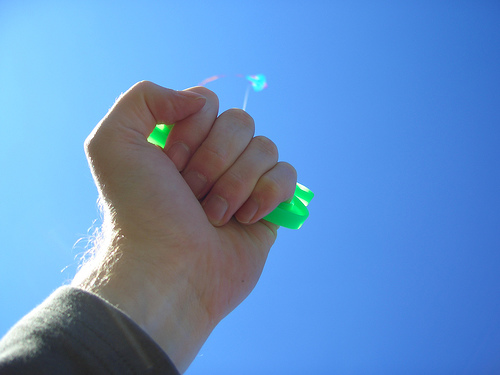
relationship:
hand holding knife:
[81, 78, 298, 308] [144, 117, 315, 235]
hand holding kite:
[81, 78, 298, 308] [195, 68, 268, 114]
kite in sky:
[195, 68, 268, 114] [0, 0, 499, 373]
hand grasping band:
[81, 78, 298, 308] [144, 117, 315, 235]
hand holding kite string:
[81, 78, 298, 308] [197, 69, 255, 115]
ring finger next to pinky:
[205, 135, 280, 231] [235, 159, 297, 225]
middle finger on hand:
[175, 107, 256, 205] [81, 78, 298, 308]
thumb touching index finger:
[94, 82, 206, 145] [163, 80, 219, 176]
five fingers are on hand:
[124, 77, 298, 192] [81, 78, 298, 308]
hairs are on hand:
[49, 197, 110, 283] [81, 78, 298, 308]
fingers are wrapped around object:
[124, 77, 298, 192] [144, 117, 315, 235]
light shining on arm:
[2, 2, 127, 364] [1, 236, 214, 374]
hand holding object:
[81, 78, 298, 308] [144, 117, 315, 235]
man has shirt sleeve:
[1, 70, 306, 373] [0, 274, 179, 374]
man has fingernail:
[1, 70, 306, 373] [203, 193, 227, 223]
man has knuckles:
[1, 70, 306, 373] [124, 77, 298, 192]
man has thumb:
[1, 70, 306, 373] [94, 82, 206, 145]